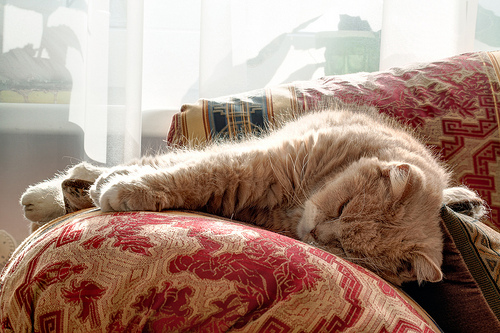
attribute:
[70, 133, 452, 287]
cat — sleeping, yellow, striped, brown, white, hairy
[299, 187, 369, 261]
face — angry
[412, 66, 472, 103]
cushion — red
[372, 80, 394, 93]
cushion — tan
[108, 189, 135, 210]
paws — white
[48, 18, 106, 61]
window — white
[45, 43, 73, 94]
sunlight — shining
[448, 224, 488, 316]
pillow — red, flowered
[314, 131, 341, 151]
fur — fluffy, yellow, orange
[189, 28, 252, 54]
light — reflecting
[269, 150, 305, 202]
fur — orange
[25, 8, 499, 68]
room — white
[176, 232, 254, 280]
arm rest — patterned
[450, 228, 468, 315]
throw pillow — patterned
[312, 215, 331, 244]
nose — brown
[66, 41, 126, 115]
curtain — sheer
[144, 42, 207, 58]
shades — white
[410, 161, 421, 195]
ears — brown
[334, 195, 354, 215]
eyes — closed